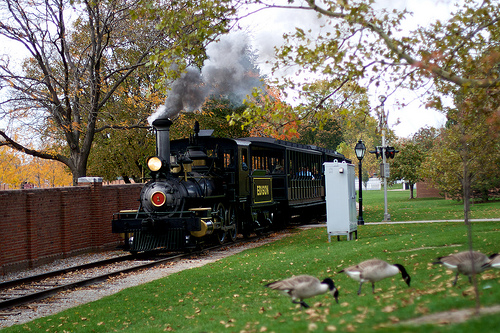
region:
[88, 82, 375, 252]
A passenger train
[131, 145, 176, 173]
The headlight is turned on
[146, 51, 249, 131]
Steam coming out from the top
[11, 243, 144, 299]
Rocks all over the tracks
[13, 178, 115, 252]
A wall next to the train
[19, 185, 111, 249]
The wall is made of brick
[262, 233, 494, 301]
Three birds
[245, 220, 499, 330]
The birds are eating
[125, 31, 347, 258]
train on a rail in a park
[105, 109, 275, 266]
engine of a train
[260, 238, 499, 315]
geese on the ground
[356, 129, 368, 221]
black lamp post on the grass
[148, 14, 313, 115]
smoke coming from the train engine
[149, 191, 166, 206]
red circle on the front of the engine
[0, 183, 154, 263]
red brick wall on the side of the tracks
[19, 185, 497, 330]
green grass on the ground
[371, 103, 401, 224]
train light post in the grass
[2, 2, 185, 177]
large tree is loosing all of its leaves for autumn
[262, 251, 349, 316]
Black grey and white goose on the grass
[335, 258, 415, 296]
Black grey and white goose on the grass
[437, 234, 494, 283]
Black grey and white goose on the grass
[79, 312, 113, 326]
Brown leaves on the grass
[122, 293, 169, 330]
Brown leaves on the grass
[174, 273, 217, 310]
Brown leaves on the grass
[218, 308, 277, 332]
Brown leaves on the grass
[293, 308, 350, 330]
Brown leaves on the grass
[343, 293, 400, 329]
Brown leaves on the grass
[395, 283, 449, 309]
Brown leaves on the grass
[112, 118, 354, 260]
old black passenger train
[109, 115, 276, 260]
old steam powered engine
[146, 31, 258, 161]
steam coming out of smoke stack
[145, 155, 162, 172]
round headlight is on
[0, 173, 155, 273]
wall is made of red brick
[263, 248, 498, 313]
three geese standing in grass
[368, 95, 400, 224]
railroad crossing signal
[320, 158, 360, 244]
tall gray electrical box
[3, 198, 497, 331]
brown dead leaves on the ground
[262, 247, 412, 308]
two geese are pecking off the ground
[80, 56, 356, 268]
train on the track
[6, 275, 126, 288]
track train is on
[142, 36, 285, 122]
steam coming from train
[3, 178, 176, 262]
brick wall near train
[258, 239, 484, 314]
lawn with green space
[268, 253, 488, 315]
birds on the lawn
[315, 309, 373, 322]
leaves on the lawn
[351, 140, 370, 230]
light on a post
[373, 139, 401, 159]
lights at rail crossing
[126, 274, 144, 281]
rocks and gravel near track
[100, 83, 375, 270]
black train that is smoking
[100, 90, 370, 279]
black train that is smoking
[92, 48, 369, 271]
black train that is smoking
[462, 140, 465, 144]
A green leaf on a plant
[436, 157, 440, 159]
A green leaf on a plant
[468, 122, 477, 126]
A green leaf on a plant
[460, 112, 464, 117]
A green leaf on a plant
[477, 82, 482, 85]
A green leaf on a plant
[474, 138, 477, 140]
A green leaf on a plant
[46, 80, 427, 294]
train on the tracks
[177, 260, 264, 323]
grass next to the train